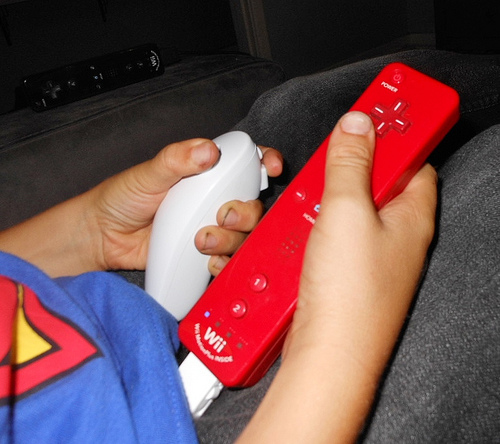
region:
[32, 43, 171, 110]
Black game controller on arm of chair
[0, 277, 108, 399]
Blue shirt with red and yellow Superman logo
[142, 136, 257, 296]
Boy holding white game controller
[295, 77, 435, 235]
Boy holding red game controller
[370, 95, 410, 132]
Directional button on Wii controller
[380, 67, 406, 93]
Power button on Wii controller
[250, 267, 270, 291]
"1" button on Wii controller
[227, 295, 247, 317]
"2" button on Wii controller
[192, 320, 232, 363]
Red controller with white writing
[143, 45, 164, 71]
Black controller with white writing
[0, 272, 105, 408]
The bottom of the Superman logo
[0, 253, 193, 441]
A blue shirt with a Superman logo on it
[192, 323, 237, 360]
A Wii logo on a red controller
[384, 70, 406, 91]
The power button on the controller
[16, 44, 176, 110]
A black Wii controller on the sofa armrest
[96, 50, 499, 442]
A pair of gray jeans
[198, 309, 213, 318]
A white light lit up on the controller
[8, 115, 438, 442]
A person's hands wrapped around controllers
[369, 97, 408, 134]
A directional pad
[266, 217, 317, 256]
A speaker on the controller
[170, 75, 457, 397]
a red wii remote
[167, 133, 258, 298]
child holding a video game controller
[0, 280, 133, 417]
part of a superman logo on a tshirt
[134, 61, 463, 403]
a child holding video game controllers in his hands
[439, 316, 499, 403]
blue denim jeans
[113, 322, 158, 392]
bright blue cotton tshirt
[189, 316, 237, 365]
Wii video game system logo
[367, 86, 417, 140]
a pad to control video game play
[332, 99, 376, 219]
right hand thumb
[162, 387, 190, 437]
hem of a tshirt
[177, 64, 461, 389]
Red Wii remote a kid is holding.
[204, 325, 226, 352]
Wii in white letters on the bottom of a red remote.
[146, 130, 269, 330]
White nun-chuck in the left hand of a kid.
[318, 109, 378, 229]
A right hand thumb.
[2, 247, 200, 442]
A blue shirt with a red and yellow symbol on it.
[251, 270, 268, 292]
Round red button with the number 1 on it.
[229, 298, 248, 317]
Red round button with the number 2 on it.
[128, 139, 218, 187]
The left thumb on a hand.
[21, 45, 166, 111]
A black remote lying to the left of a person.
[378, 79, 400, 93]
The white word POWER.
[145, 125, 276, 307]
Boy holding white controller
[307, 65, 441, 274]
Boy holding red controller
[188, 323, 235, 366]
Red Wii controller with white writing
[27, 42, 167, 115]
Black controller laying on arm of chair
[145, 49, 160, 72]
Black Wii controller with white writing